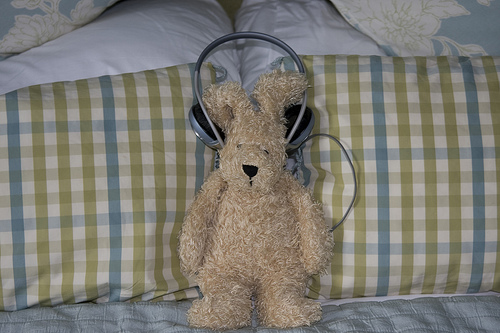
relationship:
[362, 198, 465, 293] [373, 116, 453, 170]
part of striped patterned pillow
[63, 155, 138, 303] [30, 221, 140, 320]
part of striped patterned pillow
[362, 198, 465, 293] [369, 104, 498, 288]
part of striped patterned pillow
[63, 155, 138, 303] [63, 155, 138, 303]
part of striped patterned part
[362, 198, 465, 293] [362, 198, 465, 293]
part of striped patterned part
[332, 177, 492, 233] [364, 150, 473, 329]
part of striped patterned pillow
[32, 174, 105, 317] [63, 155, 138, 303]
part of striped patterned part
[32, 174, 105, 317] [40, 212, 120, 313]
part of striped patterned pillow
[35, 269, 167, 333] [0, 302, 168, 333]
blanket called a blanket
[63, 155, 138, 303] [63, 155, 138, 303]
part with white yellow and blue part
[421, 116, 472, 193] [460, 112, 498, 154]
three pillows on left side of bed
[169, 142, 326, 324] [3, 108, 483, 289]
stuffed animals standing on bed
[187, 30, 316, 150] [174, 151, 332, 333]
ear phones for stuffed animal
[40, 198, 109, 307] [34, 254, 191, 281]
long lines on a pillow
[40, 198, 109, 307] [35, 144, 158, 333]
long lines on a pillow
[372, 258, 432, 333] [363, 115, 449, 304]
long lines on a pillow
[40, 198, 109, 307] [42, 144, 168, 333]
long lines on a pillow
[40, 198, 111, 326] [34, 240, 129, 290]
long lines on a pillow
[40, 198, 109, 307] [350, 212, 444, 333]
long lines on a pillow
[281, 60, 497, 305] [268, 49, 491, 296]
lines on a pillow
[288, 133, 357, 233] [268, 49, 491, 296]
lines on a pillow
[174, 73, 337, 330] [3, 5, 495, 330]
stuffed animals on a bed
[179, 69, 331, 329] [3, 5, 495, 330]
rabbit on a bed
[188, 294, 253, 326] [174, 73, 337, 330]
foot on a stuffed animals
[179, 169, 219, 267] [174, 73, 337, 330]
arm on a stuffed animals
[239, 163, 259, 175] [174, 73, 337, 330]
nose on a stuffed animals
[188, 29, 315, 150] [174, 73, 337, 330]
ear phones on a stuffed animals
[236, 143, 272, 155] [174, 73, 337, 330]
eyes on a stuffed animals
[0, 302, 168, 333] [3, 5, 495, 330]
blanket on a bed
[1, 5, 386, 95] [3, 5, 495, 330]
pillows on a bed